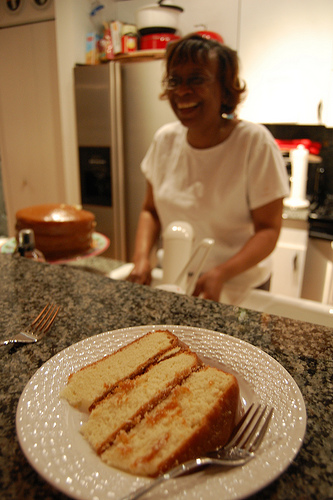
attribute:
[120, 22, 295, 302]
woman — smiling, laughing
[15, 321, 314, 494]
plate — white, round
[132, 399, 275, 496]
fork — silver, long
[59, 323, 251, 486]
cake — golden, brown, chocolate, iced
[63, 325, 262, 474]
slice — cake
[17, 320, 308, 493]
saucer — glistening, white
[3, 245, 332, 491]
counter — marble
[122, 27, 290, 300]
lady — standing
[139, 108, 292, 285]
shirt — white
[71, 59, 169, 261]
refrigerator — here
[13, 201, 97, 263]
cake — large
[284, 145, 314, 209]
roll — towels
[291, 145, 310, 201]
towels — paper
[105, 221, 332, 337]
sink — white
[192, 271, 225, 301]
hand — here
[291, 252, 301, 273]
handle — cabnet's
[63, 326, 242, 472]
piece — cake, ready to eat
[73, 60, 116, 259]
door — refrigerator, refrigerator's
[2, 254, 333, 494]
countertop — granite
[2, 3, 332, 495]
kitchen — modern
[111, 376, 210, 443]
bits — caramel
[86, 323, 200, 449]
icing — caramel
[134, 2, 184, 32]
crock pot — white